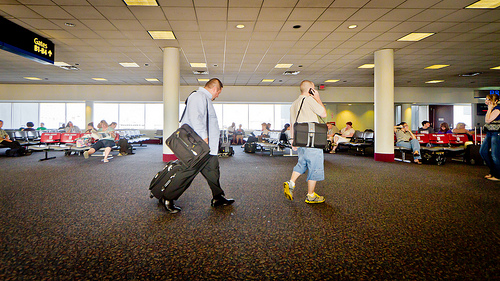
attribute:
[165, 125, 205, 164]
bags — luggage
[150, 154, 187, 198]
bags — luggage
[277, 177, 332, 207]
shoes — yellow, grey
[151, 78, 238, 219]
man — walking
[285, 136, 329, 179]
shorts — blue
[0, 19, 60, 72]
board — black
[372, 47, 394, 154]
pole — white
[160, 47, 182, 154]
pole — white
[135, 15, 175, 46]
light — bright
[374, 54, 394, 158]
beam — round, white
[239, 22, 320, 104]
light — bright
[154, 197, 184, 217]
shoe — black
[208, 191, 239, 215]
shoe — black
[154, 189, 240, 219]
shoes — black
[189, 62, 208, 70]
light — bright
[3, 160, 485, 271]
floor — speckled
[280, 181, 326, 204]
shoes — yellow